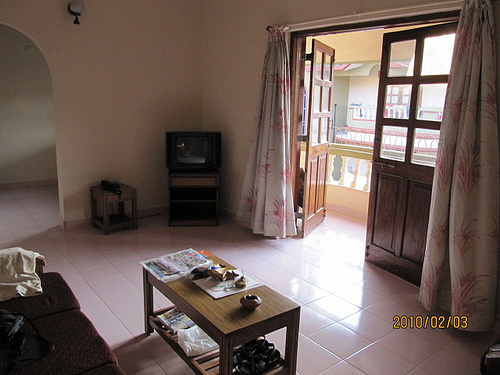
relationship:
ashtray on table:
[240, 293, 260, 311] [141, 255, 302, 374]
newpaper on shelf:
[157, 306, 193, 332] [149, 304, 284, 372]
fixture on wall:
[65, 0, 83, 24] [1, 1, 213, 226]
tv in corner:
[165, 131, 221, 173] [178, 1, 231, 209]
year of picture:
[391, 314, 424, 331] [2, 2, 500, 375]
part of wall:
[102, 49, 187, 92] [1, 1, 213, 226]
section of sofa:
[1, 307, 119, 374] [1, 248, 124, 374]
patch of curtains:
[416, 10, 477, 309] [417, 0, 500, 332]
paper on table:
[139, 247, 213, 283] [141, 255, 302, 374]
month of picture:
[430, 315, 447, 332] [2, 2, 500, 375]